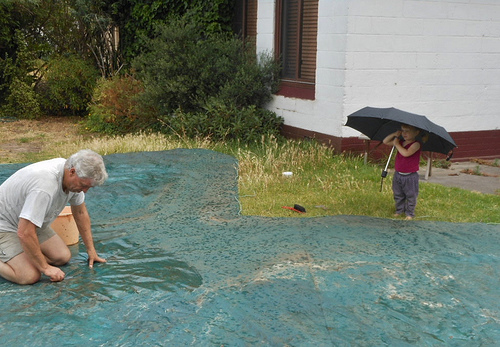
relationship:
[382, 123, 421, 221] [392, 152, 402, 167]
child in red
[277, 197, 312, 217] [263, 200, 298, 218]
brush on ground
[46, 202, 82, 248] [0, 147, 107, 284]
bucket beside man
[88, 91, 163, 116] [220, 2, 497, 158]
bushes beside house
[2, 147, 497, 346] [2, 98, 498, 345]
plastic on ground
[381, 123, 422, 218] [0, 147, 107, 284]
child watching man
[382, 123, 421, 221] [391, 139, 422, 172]
child wearing shirt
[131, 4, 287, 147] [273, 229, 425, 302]
brush on ground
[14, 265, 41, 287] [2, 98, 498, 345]
knee on ground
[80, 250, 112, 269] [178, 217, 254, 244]
hand on ground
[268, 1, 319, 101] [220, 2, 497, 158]
window on house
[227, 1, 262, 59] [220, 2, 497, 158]
window on house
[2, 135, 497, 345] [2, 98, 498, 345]
tarp on ground